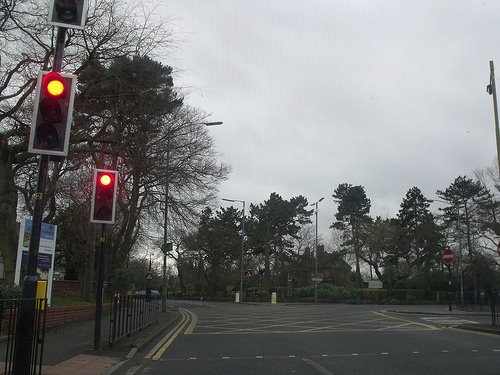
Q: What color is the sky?
A: Grey.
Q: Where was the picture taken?
A: On a street.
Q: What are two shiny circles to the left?
A: Traffic lights.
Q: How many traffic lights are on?
A: Two.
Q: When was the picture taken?
A: At dusk.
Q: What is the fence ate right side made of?
A: Metal.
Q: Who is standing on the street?
A: No one.